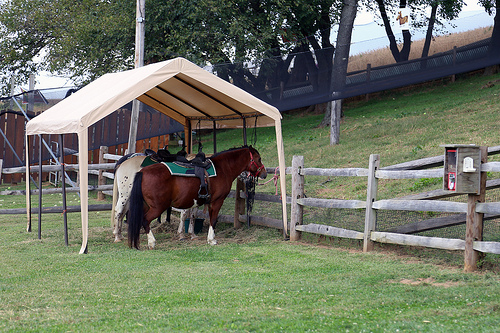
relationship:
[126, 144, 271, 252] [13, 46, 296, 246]
horse under canopy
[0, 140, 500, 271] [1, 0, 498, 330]
fence around pasture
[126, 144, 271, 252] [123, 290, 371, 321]
horse in grass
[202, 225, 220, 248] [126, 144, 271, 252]
white feet of horse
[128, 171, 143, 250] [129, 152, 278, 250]
tail of horse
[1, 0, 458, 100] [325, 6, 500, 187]
trees on hill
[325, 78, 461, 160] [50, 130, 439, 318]
hill in pasture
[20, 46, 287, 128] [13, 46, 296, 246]
roof of canopy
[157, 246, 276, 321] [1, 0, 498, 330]
grass in pasture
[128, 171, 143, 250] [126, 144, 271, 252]
tail of horse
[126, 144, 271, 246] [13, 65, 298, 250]
horse under tent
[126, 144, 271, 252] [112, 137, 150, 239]
horse standing by horse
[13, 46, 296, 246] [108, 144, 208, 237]
canopy over horses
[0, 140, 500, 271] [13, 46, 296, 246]
fence by canopy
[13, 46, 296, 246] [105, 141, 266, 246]
canopy with horses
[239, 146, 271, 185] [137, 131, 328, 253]
red bridal on horse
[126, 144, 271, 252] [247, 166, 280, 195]
horse tied with rope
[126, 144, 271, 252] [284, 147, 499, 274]
horse tied to fence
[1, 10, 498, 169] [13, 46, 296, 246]
mesh beside canopy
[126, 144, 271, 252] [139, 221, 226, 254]
horse with feet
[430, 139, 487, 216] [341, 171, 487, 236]
box on a fence